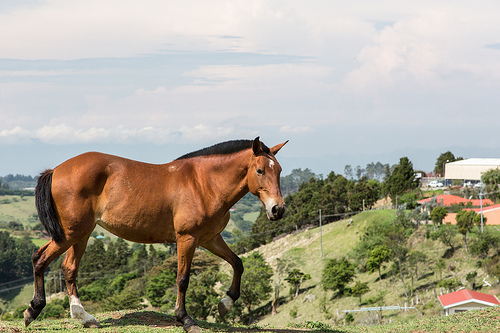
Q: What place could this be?
A: It is a field.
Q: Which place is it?
A: It is a field.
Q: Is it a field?
A: Yes, it is a field.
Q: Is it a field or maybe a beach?
A: It is a field.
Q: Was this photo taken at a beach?
A: No, the picture was taken in a field.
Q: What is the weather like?
A: It is cloudy.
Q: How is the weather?
A: It is cloudy.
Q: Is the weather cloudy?
A: Yes, it is cloudy.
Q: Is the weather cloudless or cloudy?
A: It is cloudy.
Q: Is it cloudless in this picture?
A: No, it is cloudy.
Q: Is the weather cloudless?
A: No, it is cloudy.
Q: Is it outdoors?
A: Yes, it is outdoors.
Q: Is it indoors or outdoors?
A: It is outdoors.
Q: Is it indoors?
A: No, it is outdoors.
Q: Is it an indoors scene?
A: No, it is outdoors.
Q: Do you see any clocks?
A: No, there are no clocks.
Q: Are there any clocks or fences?
A: No, there are no clocks or fences.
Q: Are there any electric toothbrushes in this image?
A: No, there are no electric toothbrushes.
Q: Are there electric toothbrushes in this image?
A: No, there are no electric toothbrushes.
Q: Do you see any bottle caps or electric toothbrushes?
A: No, there are no electric toothbrushes or bottle caps.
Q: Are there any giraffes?
A: No, there are no giraffes.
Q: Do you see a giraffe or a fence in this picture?
A: No, there are no giraffes or fences.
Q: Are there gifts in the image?
A: No, there are no gifts.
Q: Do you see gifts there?
A: No, there are no gifts.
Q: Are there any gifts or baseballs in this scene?
A: No, there are no gifts or baseballs.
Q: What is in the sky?
A: The clouds are in the sky.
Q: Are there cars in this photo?
A: No, there are no cars.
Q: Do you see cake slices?
A: No, there are no cake slices.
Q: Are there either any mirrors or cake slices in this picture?
A: No, there are no cake slices or mirrors.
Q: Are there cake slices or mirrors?
A: No, there are no cake slices or mirrors.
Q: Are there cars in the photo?
A: No, there are no cars.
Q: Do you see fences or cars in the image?
A: No, there are no cars or fences.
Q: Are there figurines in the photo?
A: No, there are no figurines.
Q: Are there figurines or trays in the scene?
A: No, there are no figurines or trays.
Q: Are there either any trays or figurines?
A: No, there are no figurines or trays.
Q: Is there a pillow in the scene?
A: No, there are no pillows.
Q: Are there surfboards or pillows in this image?
A: No, there are no pillows or surfboards.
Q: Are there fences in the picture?
A: No, there are no fences.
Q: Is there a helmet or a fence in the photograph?
A: No, there are no fences or helmets.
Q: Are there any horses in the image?
A: Yes, there is a horse.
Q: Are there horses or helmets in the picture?
A: Yes, there is a horse.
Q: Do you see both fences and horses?
A: No, there is a horse but no fences.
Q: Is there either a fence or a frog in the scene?
A: No, there are no fences or frogs.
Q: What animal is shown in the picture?
A: The animal is a horse.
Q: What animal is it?
A: The animal is a horse.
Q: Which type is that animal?
A: This is a horse.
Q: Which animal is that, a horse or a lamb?
A: This is a horse.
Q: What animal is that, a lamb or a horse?
A: This is a horse.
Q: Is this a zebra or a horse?
A: This is a horse.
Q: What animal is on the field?
A: The horse is on the field.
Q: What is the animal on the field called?
A: The animal is a horse.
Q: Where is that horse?
A: The horse is on the field.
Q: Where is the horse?
A: The horse is on the field.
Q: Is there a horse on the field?
A: Yes, there is a horse on the field.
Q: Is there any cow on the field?
A: No, there is a horse on the field.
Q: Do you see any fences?
A: No, there are no fences.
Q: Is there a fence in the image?
A: No, there are no fences.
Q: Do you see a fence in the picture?
A: No, there are no fences.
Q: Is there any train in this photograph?
A: No, there are no trains.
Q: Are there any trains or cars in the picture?
A: No, there are no trains or cars.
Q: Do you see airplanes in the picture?
A: No, there are no airplanes.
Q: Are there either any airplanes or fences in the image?
A: No, there are no airplanes or fences.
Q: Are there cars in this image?
A: No, there are no cars.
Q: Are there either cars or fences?
A: No, there are no cars or fences.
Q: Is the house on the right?
A: Yes, the house is on the right of the image.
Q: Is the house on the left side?
A: No, the house is on the right of the image.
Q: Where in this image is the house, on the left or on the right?
A: The house is on the right of the image.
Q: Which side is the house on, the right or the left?
A: The house is on the right of the image.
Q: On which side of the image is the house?
A: The house is on the right of the image.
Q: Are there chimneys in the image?
A: No, there are no chimneys.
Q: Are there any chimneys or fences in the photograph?
A: No, there are no chimneys or fences.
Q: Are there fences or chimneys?
A: No, there are no chimneys or fences.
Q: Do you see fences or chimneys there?
A: No, there are no chimneys or fences.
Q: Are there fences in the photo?
A: No, there are no fences.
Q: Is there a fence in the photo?
A: No, there are no fences.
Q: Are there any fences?
A: No, there are no fences.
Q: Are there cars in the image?
A: No, there are no cars.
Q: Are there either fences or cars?
A: No, there are no cars or fences.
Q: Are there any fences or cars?
A: No, there are no fences or cars.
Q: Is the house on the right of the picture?
A: Yes, the house is on the right of the image.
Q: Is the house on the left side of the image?
A: No, the house is on the right of the image.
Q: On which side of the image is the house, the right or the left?
A: The house is on the right of the image.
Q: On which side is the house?
A: The house is on the right of the image.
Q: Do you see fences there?
A: No, there are no fences.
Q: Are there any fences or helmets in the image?
A: No, there are no fences or helmets.